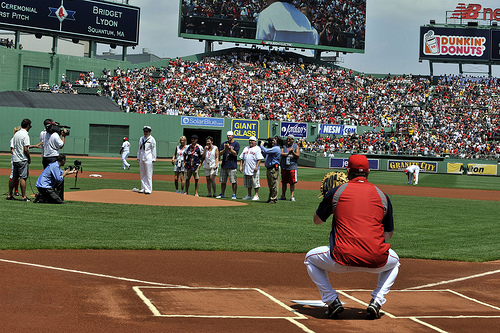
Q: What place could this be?
A: It is a field.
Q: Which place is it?
A: It is a field.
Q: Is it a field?
A: Yes, it is a field.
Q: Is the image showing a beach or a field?
A: It is showing a field.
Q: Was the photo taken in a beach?
A: No, the picture was taken in a field.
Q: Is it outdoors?
A: Yes, it is outdoors.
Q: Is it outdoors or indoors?
A: It is outdoors.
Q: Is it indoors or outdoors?
A: It is outdoors.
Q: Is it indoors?
A: No, it is outdoors.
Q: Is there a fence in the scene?
A: No, there are no fences.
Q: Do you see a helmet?
A: No, there are no helmets.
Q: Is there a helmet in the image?
A: No, there are no helmets.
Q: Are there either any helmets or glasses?
A: No, there are no helmets or glasses.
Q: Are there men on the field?
A: Yes, there is a man on the field.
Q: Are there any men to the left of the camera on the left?
A: Yes, there is a man to the left of the camera.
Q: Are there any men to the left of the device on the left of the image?
A: Yes, there is a man to the left of the camera.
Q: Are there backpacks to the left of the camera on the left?
A: No, there is a man to the left of the camera.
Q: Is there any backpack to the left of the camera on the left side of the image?
A: No, there is a man to the left of the camera.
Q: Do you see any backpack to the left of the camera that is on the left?
A: No, there is a man to the left of the camera.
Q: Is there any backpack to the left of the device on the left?
A: No, there is a man to the left of the camera.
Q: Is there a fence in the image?
A: No, there are no fences.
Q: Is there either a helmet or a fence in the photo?
A: No, there are no fences or helmets.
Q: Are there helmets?
A: No, there are no helmets.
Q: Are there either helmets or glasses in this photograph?
A: No, there are no helmets or glasses.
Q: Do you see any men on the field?
A: Yes, there is a man on the field.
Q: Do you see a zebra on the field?
A: No, there is a man on the field.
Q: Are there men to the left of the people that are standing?
A: Yes, there is a man to the left of the people.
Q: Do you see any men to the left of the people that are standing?
A: Yes, there is a man to the left of the people.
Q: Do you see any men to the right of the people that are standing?
A: No, the man is to the left of the people.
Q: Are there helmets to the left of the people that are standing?
A: No, there is a man to the left of the people.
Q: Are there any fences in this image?
A: No, there are no fences.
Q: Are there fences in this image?
A: No, there are no fences.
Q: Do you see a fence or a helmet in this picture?
A: No, there are no fences or helmets.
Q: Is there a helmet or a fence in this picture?
A: No, there are no fences or helmets.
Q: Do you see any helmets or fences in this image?
A: No, there are no fences or helmets.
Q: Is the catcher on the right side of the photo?
A: Yes, the catcher is on the right of the image.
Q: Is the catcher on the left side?
A: No, the catcher is on the right of the image.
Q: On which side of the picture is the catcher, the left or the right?
A: The catcher is on the right of the image.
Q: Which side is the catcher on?
A: The catcher is on the right of the image.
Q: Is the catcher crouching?
A: Yes, the catcher is crouching.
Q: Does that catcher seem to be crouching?
A: Yes, the catcher is crouching.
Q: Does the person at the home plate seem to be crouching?
A: Yes, the catcher is crouching.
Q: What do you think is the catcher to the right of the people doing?
A: The catcher is crouching.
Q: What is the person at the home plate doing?
A: The catcher is crouching.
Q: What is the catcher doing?
A: The catcher is crouching.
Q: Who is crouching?
A: The catcher is crouching.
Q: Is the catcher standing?
A: No, the catcher is crouching.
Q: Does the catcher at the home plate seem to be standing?
A: No, the catcher is crouching.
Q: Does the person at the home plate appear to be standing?
A: No, the catcher is crouching.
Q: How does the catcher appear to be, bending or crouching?
A: The catcher is crouching.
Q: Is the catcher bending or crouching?
A: The catcher is crouching.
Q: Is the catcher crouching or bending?
A: The catcher is crouching.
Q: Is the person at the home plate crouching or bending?
A: The catcher is crouching.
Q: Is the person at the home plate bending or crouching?
A: The catcher is crouching.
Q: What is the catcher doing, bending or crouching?
A: The catcher is crouching.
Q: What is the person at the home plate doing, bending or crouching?
A: The catcher is crouching.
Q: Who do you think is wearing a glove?
A: The catcher is wearing a glove.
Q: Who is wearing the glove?
A: The catcher is wearing a glove.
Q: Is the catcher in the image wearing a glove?
A: Yes, the catcher is wearing a glove.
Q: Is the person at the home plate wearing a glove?
A: Yes, the catcher is wearing a glove.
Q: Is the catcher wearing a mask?
A: No, the catcher is wearing a glove.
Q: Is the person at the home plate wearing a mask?
A: No, the catcher is wearing a glove.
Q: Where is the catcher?
A: The catcher is at the home plate.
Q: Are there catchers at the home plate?
A: Yes, there is a catcher at the home plate.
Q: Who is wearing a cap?
A: The catcher is wearing a cap.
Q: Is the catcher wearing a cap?
A: Yes, the catcher is wearing a cap.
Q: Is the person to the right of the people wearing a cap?
A: Yes, the catcher is wearing a cap.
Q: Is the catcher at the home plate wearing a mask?
A: No, the catcher is wearing a cap.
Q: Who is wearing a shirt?
A: The catcher is wearing a shirt.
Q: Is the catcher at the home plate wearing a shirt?
A: Yes, the catcher is wearing a shirt.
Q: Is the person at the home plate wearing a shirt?
A: Yes, the catcher is wearing a shirt.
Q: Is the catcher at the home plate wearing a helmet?
A: No, the catcher is wearing a shirt.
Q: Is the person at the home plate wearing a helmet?
A: No, the catcher is wearing a shirt.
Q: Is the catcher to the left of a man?
A: No, the catcher is to the right of a man.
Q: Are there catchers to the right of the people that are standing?
A: Yes, there is a catcher to the right of the people.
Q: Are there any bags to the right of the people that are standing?
A: No, there is a catcher to the right of the people.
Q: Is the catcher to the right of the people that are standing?
A: Yes, the catcher is to the right of the people.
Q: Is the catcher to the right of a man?
A: Yes, the catcher is to the right of a man.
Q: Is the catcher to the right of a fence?
A: No, the catcher is to the right of a man.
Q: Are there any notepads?
A: No, there are no notepads.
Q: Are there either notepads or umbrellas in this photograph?
A: No, there are no notepads or umbrellas.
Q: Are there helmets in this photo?
A: No, there are no helmets.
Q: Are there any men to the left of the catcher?
A: Yes, there is a man to the left of the catcher.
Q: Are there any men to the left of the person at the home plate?
A: Yes, there is a man to the left of the catcher.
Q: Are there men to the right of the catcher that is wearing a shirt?
A: No, the man is to the left of the catcher.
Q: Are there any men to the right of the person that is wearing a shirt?
A: No, the man is to the left of the catcher.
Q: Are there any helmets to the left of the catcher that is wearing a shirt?
A: No, there is a man to the left of the catcher.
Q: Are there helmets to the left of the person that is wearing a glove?
A: No, there is a man to the left of the catcher.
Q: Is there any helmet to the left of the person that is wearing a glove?
A: No, there is a man to the left of the catcher.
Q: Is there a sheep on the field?
A: No, there is a man on the field.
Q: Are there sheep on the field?
A: No, there is a man on the field.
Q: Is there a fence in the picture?
A: No, there are no fences.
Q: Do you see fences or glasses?
A: No, there are no fences or glasses.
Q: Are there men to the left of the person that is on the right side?
A: Yes, there is a man to the left of the catcher.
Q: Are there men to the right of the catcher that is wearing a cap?
A: No, the man is to the left of the catcher.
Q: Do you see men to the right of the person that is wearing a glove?
A: No, the man is to the left of the catcher.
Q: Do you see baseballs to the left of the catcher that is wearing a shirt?
A: No, there is a man to the left of the catcher.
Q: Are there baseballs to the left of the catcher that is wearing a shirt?
A: No, there is a man to the left of the catcher.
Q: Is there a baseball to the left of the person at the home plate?
A: No, there is a man to the left of the catcher.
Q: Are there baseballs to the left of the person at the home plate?
A: No, there is a man to the left of the catcher.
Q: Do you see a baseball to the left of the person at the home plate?
A: No, there is a man to the left of the catcher.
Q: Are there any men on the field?
A: Yes, there is a man on the field.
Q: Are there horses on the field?
A: No, there is a man on the field.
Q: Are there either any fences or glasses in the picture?
A: No, there are no fences or glasses.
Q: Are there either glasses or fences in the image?
A: No, there are no fences or glasses.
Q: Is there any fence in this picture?
A: No, there are no fences.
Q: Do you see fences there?
A: No, there are no fences.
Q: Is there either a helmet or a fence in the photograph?
A: No, there are no fences or helmets.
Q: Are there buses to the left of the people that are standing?
A: No, there is a man to the left of the people.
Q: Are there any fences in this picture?
A: No, there are no fences.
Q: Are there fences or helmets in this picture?
A: No, there are no fences or helmets.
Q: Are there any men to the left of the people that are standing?
A: Yes, there is a man to the left of the people.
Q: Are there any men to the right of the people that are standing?
A: No, the man is to the left of the people.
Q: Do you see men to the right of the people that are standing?
A: No, the man is to the left of the people.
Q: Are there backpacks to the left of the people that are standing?
A: No, there is a man to the left of the people.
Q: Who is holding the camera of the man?
A: The man is holding the camera.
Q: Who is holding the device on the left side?
A: The man is holding the camera.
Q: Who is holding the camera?
A: The man is holding the camera.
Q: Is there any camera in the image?
A: Yes, there is a camera.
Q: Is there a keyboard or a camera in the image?
A: Yes, there is a camera.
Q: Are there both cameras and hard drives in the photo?
A: No, there is a camera but no hard drives.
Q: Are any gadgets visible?
A: No, there are no gadgets.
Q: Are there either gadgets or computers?
A: No, there are no gadgets or computers.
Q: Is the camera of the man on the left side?
A: Yes, the camera is on the left of the image.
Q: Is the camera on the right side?
A: No, the camera is on the left of the image.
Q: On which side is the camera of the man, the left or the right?
A: The camera is on the left of the image.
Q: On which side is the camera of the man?
A: The camera is on the left of the image.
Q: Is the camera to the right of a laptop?
A: No, the camera is to the right of a man.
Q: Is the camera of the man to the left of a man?
A: Yes, the camera is to the left of a man.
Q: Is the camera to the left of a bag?
A: No, the camera is to the left of a man.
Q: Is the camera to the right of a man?
A: No, the camera is to the left of a man.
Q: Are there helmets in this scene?
A: No, there are no helmets.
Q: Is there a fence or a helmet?
A: No, there are no helmets or fences.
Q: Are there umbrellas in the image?
A: No, there are no umbrellas.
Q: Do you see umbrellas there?
A: No, there are no umbrellas.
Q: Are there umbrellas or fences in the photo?
A: No, there are no umbrellas or fences.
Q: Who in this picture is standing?
A: The people are standing.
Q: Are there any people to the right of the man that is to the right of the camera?
A: Yes, there are people to the right of the man.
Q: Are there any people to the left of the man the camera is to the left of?
A: No, the people are to the right of the man.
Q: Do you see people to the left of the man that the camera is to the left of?
A: No, the people are to the right of the man.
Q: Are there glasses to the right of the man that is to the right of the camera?
A: No, there are people to the right of the man.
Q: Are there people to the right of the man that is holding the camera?
A: Yes, there are people to the right of the man.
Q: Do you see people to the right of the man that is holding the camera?
A: Yes, there are people to the right of the man.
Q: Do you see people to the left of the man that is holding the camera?
A: No, the people are to the right of the man.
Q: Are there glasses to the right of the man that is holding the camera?
A: No, there are people to the right of the man.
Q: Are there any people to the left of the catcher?
A: Yes, there are people to the left of the catcher.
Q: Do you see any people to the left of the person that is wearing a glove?
A: Yes, there are people to the left of the catcher.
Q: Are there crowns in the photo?
A: No, there are no crowns.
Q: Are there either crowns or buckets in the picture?
A: No, there are no crowns or buckets.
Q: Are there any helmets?
A: No, there are no helmets.